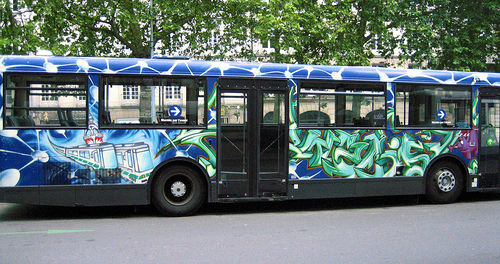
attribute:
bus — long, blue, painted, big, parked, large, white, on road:
[1, 55, 500, 198]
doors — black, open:
[221, 81, 288, 195]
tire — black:
[152, 160, 204, 210]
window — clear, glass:
[297, 88, 384, 128]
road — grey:
[5, 196, 500, 263]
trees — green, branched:
[5, 3, 498, 73]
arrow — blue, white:
[439, 110, 445, 123]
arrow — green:
[4, 229, 97, 242]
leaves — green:
[9, 4, 390, 52]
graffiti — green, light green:
[290, 92, 478, 185]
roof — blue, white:
[2, 55, 499, 85]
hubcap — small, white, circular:
[172, 182, 185, 196]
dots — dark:
[442, 171, 451, 177]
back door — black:
[216, 84, 254, 198]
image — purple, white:
[454, 128, 480, 158]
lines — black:
[39, 163, 120, 182]